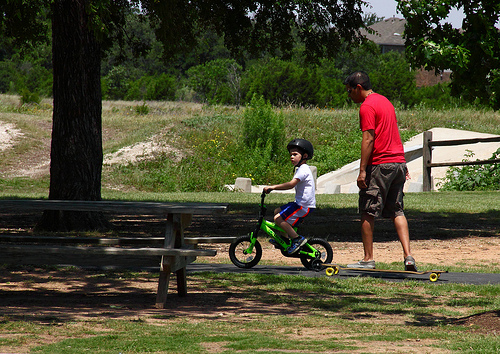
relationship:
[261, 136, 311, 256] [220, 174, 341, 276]
boy riding a bike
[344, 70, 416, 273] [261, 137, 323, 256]
man standing behind boy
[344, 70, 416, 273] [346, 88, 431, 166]
man wearing shirt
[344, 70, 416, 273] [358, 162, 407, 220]
man wearing shorts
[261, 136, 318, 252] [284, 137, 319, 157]
boy wearing helmet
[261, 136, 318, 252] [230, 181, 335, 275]
boy riding bike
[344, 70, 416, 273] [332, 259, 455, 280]
man riding skateboard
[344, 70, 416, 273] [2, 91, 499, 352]
man in park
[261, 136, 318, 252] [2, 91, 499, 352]
boy in park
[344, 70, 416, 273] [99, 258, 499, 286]
man on sidewalk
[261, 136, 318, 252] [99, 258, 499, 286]
boy on sidewalk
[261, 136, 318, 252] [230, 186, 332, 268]
boy riding bike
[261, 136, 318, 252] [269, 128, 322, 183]
boy wearing helmet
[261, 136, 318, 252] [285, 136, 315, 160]
boy wearing helmet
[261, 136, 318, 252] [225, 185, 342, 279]
boy riding bike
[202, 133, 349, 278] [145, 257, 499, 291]
bike on sidewalk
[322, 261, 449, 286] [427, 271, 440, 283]
skateboard with wheels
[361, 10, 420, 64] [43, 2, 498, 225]
building beyond trees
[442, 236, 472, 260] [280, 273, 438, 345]
dirt on ground